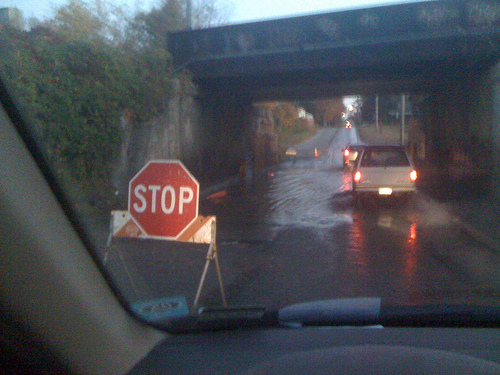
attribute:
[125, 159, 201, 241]
stop sign — white, red, outlined, eight sided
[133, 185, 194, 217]
letters — white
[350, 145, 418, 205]
car — braking, white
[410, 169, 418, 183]
tail light — red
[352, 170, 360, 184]
tail light — red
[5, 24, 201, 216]
shrub — green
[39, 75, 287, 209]
wall — concrete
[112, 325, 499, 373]
dashboard — gray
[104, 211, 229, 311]
barrier — white, orange, striped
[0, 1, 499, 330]
window — glass, clear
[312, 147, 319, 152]
traffic cone — orange, white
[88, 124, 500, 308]
road — flooded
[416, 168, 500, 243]
sidewalk — concrete